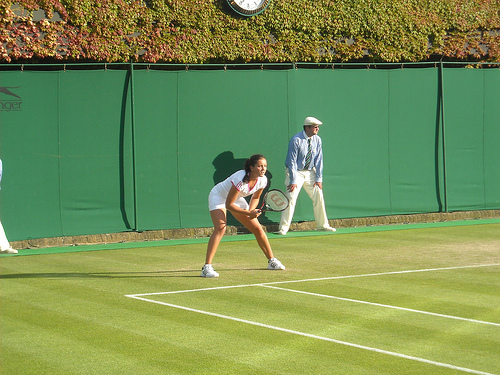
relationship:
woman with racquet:
[198, 150, 296, 276] [257, 189, 294, 214]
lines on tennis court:
[127, 269, 498, 372] [2, 227, 499, 374]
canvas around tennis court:
[4, 69, 498, 234] [2, 227, 499, 374]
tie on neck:
[303, 138, 317, 171] [302, 129, 311, 135]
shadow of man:
[210, 149, 284, 218] [278, 114, 334, 233]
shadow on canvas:
[210, 149, 284, 218] [4, 69, 498, 234]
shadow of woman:
[2, 267, 202, 281] [198, 150, 296, 276]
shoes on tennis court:
[194, 258, 287, 277] [2, 227, 499, 374]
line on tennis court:
[130, 261, 499, 306] [2, 227, 499, 374]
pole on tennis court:
[438, 63, 450, 215] [2, 227, 499, 374]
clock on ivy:
[226, 1, 270, 18] [2, 4, 496, 56]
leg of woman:
[204, 192, 223, 279] [198, 150, 296, 276]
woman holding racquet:
[198, 150, 296, 276] [257, 189, 294, 214]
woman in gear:
[198, 150, 296, 276] [203, 172, 290, 225]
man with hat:
[278, 114, 334, 233] [301, 114, 321, 126]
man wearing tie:
[278, 114, 334, 233] [303, 138, 317, 171]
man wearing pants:
[278, 114, 334, 233] [277, 170, 333, 228]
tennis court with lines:
[2, 227, 499, 374] [127, 269, 498, 372]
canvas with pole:
[4, 69, 498, 234] [438, 63, 450, 215]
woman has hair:
[198, 150, 296, 276] [242, 153, 265, 170]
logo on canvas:
[1, 81, 27, 117] [4, 69, 498, 234]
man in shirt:
[278, 114, 334, 233] [286, 127, 327, 184]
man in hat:
[278, 114, 334, 233] [301, 114, 321, 126]